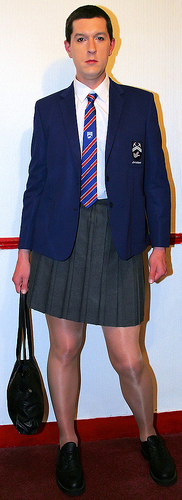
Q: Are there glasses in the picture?
A: No, there are no glasses.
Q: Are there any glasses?
A: No, there are no glasses.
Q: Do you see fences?
A: No, there are no fences.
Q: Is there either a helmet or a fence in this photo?
A: No, there are no fences or helmets.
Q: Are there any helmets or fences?
A: No, there are no fences or helmets.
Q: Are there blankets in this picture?
A: No, there are no blankets.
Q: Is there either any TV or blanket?
A: No, there are no blankets or televisions.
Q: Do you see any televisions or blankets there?
A: No, there are no blankets or televisions.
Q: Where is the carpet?
A: The carpet is on the floor.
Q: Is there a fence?
A: No, there are no fences.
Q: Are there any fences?
A: No, there are no fences.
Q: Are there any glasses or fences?
A: No, there are no fences or glasses.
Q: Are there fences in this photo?
A: No, there are no fences.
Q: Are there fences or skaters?
A: No, there are no fences or skaters.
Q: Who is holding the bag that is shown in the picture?
A: The man is holding the bag.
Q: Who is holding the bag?
A: The man is holding the bag.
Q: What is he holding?
A: The man is holding the bag.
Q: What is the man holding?
A: The man is holding the bag.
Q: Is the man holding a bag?
A: Yes, the man is holding a bag.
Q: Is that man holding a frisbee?
A: No, the man is holding a bag.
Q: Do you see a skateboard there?
A: No, there are no skateboards.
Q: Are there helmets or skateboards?
A: No, there are no skateboards or helmets.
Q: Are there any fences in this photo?
A: No, there are no fences.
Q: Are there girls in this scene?
A: No, there are no girls.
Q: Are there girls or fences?
A: No, there are no girls or fences.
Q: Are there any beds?
A: No, there are no beds.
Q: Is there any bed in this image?
A: No, there are no beds.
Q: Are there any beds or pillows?
A: No, there are no beds or pillows.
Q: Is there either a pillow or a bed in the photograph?
A: No, there are no beds or pillows.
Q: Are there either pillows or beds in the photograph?
A: No, there are no beds or pillows.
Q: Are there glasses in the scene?
A: No, there are no glasses.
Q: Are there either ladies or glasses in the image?
A: No, there are no glasses or ladies.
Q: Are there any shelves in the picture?
A: No, there are no shelves.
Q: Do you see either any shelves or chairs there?
A: No, there are no shelves or chairs.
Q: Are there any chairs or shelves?
A: No, there are no shelves or chairs.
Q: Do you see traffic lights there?
A: No, there are no traffic lights.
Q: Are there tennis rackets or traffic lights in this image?
A: No, there are no traffic lights or tennis rackets.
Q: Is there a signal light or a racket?
A: No, there are no traffic lights or rackets.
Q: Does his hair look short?
A: Yes, the hair is short.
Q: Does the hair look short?
A: Yes, the hair is short.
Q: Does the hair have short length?
A: Yes, the hair is short.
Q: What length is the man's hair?
A: The hair is short.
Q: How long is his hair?
A: The hair is short.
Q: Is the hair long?
A: No, the hair is short.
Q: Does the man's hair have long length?
A: No, the hair is short.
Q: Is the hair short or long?
A: The hair is short.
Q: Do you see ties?
A: Yes, there is a tie.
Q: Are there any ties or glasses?
A: Yes, there is a tie.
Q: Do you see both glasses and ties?
A: No, there is a tie but no glasses.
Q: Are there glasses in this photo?
A: No, there are no glasses.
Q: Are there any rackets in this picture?
A: No, there are no rackets.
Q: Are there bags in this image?
A: Yes, there is a bag.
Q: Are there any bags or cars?
A: Yes, there is a bag.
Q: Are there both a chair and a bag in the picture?
A: No, there is a bag but no chairs.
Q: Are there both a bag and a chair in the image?
A: No, there is a bag but no chairs.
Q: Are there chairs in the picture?
A: No, there are no chairs.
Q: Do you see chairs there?
A: No, there are no chairs.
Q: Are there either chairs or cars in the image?
A: No, there are no chairs or cars.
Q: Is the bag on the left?
A: Yes, the bag is on the left of the image.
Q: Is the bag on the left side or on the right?
A: The bag is on the left of the image.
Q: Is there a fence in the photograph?
A: No, there are no fences.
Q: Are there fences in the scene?
A: No, there are no fences.